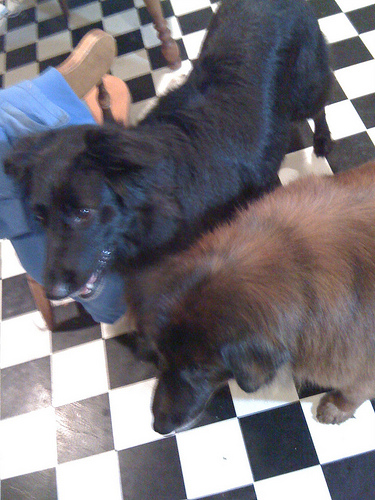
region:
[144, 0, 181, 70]
wood leg of furniture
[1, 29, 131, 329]
clothing on wood chair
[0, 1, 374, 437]
two dogs on checkered floor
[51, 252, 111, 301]
open mouth of dog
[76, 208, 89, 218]
light reflection in eye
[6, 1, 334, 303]
black coat on dog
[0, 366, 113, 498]
The floor is black and white.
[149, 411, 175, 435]
The dogs nose is black in color.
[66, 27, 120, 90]
The chair is light brown.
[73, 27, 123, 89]
The chair is made from wood.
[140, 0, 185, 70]
The table leg is brown in color.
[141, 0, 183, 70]
The table leg is made from wood.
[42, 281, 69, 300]
The dog has a black nose.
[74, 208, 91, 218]
The dogs eye is brown.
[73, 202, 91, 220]
The dogs eye is round.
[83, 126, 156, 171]
The dogs ear is black.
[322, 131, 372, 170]
black tile on floor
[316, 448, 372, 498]
black tile on floor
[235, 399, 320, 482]
black tile on floor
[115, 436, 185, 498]
black tile on floor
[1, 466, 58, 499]
black tile on floor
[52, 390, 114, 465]
black tile on floor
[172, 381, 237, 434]
black tile on floor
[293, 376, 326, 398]
black tile on floor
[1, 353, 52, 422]
black tile on floor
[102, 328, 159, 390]
black tile on floor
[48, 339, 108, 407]
white floor tile next to black floor tile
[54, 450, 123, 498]
white floor tile next to black floor tile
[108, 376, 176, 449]
white floor tile next to black floor tile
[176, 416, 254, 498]
white floor tile next to black floor tile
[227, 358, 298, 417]
white floor tile next to black floor tile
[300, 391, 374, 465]
white floor tile next to black floor tile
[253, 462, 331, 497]
white floor tile next to black floor tile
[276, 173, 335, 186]
white floor tile next to black floor tile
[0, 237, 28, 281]
white floor tile next to black floor tile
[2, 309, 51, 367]
white floor tile next to black floor tile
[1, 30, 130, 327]
clothing on back of chair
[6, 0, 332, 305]
black fur on dog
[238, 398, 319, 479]
black box on floor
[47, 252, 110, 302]
open mouth of door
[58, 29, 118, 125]
back of wood chair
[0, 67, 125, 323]
blue clothing behind dog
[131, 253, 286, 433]
top of dog's head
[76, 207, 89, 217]
light reflection on eye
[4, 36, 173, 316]
the dog is black